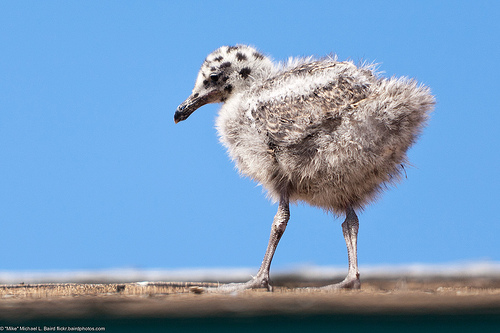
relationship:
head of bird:
[174, 43, 276, 123] [174, 43, 438, 293]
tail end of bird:
[290, 51, 437, 218] [174, 43, 438, 293]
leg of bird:
[190, 193, 291, 295] [174, 43, 438, 293]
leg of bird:
[319, 207, 362, 291] [174, 43, 438, 293]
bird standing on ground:
[174, 43, 438, 293] [1, 260, 500, 332]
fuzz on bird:
[192, 44, 437, 218] [174, 43, 438, 293]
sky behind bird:
[1, 1, 500, 273] [174, 43, 438, 293]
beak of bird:
[174, 88, 223, 123] [174, 43, 438, 293]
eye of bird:
[209, 72, 218, 81] [174, 43, 438, 293]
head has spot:
[174, 43, 276, 123] [213, 55, 224, 62]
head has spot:
[174, 43, 276, 123] [227, 45, 239, 53]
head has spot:
[174, 43, 276, 123] [218, 61, 231, 70]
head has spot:
[174, 43, 276, 123] [236, 52, 247, 61]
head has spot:
[174, 43, 276, 123] [239, 67, 251, 79]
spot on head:
[213, 55, 224, 62] [174, 43, 276, 123]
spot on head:
[227, 45, 239, 53] [174, 43, 276, 123]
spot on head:
[218, 61, 231, 70] [174, 43, 276, 123]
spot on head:
[236, 52, 247, 61] [174, 43, 276, 123]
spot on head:
[239, 67, 251, 79] [174, 43, 276, 123]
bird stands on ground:
[174, 43, 438, 293] [1, 260, 500, 332]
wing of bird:
[248, 59, 372, 147] [174, 43, 438, 293]